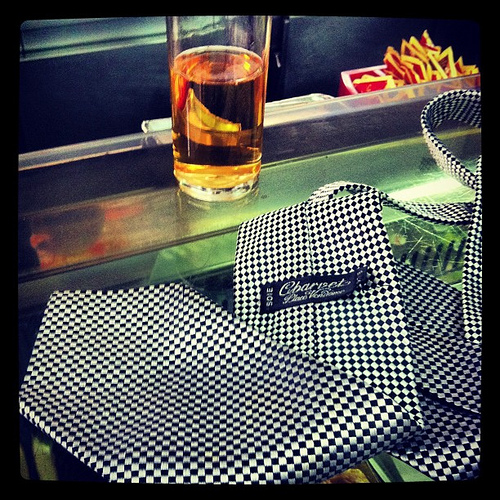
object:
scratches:
[396, 211, 467, 279]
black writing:
[400, 241, 465, 272]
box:
[337, 63, 480, 107]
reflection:
[23, 194, 149, 267]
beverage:
[170, 49, 262, 192]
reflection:
[178, 65, 235, 148]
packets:
[338, 30, 478, 106]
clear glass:
[164, 15, 273, 206]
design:
[158, 364, 181, 385]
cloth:
[19, 87, 478, 497]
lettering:
[278, 279, 352, 296]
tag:
[256, 265, 368, 317]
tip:
[47, 284, 65, 304]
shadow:
[176, 85, 256, 165]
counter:
[17, 69, 478, 479]